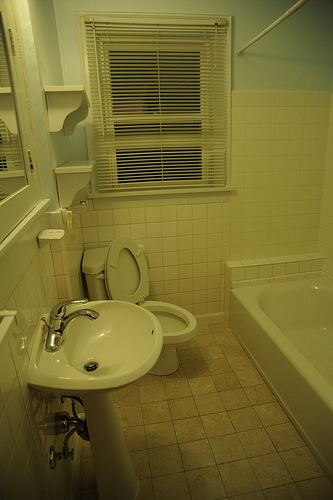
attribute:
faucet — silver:
[39, 291, 101, 328]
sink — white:
[29, 293, 163, 393]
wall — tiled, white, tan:
[48, 2, 331, 352]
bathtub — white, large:
[230, 277, 332, 454]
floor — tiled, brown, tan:
[82, 317, 332, 493]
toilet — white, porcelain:
[85, 239, 199, 378]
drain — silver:
[79, 361, 101, 372]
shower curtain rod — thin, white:
[233, 5, 307, 60]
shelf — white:
[44, 78, 89, 136]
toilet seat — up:
[102, 234, 158, 312]